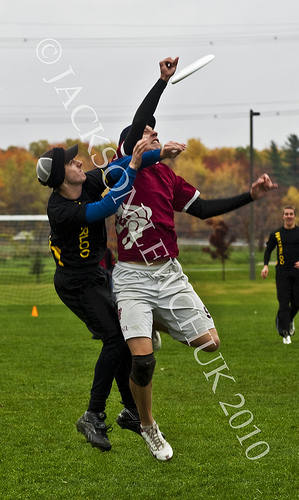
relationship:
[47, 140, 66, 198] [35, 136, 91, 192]
band on cap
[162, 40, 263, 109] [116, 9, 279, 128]
frisbee in air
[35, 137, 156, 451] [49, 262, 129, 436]
man wearing black yoga pants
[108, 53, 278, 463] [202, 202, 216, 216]
man wearing long sleeved t shirt in black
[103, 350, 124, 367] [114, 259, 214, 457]
black knee support on leg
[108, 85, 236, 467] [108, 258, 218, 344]
man wearing grey shorts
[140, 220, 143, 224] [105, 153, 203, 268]
white image on the shirt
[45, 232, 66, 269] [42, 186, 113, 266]
color writing on the shirt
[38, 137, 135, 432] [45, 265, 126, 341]
man wearing black pants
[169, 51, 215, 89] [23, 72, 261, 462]
frisbee in air by men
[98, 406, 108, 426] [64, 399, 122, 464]
black cleats on mans foot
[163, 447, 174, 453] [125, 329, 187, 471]
white cleats on mans foot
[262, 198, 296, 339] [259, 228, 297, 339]
man in black cloths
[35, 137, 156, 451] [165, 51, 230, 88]
man fighting too catch frisbee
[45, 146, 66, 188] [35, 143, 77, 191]
sweatband worn around band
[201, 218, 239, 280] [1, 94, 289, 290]
tree standing in background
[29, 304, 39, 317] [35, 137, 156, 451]
cone standing behind man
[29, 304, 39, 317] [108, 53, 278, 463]
cone standing behind man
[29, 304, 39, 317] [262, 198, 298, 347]
cone standing behind man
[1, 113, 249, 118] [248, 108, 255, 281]
electric line attached to pole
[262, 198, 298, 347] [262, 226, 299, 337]
man wearing black cloths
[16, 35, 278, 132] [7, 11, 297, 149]
light of sky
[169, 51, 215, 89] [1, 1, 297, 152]
frisbee in air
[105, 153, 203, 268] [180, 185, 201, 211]
shirt with trim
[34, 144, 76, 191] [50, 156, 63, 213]
cap with warmer